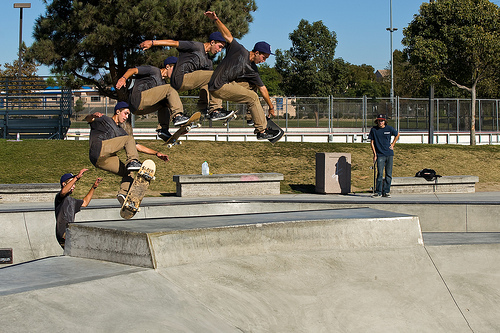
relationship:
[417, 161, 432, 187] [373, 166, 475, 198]
backpack on bench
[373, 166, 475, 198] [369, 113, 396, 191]
bench near man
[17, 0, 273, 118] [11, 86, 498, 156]
trees in front of fence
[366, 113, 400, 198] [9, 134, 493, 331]
man in skate park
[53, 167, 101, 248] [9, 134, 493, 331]
man in skate park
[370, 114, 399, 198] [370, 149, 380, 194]
man on skateboard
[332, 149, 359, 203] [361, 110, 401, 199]
shadow of man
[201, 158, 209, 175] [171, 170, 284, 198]
container on a bench